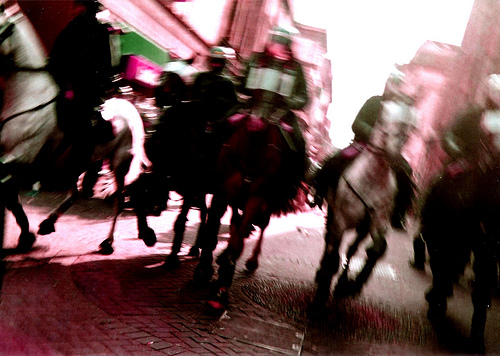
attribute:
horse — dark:
[209, 95, 314, 272]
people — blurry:
[69, 7, 491, 139]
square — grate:
[222, 310, 304, 355]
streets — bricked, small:
[15, 200, 492, 356]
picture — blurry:
[15, 11, 497, 354]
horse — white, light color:
[7, 64, 156, 223]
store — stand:
[68, 13, 179, 188]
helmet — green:
[266, 23, 296, 50]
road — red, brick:
[24, 196, 473, 343]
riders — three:
[202, 23, 412, 135]